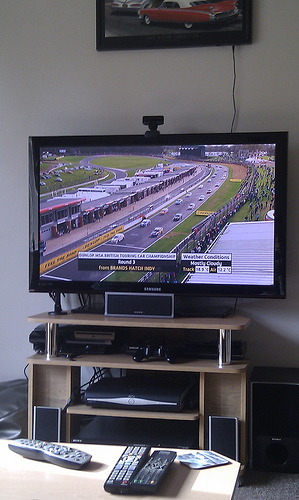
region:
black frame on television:
[14, 127, 282, 300]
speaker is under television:
[97, 281, 192, 328]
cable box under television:
[88, 375, 212, 430]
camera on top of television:
[139, 105, 168, 134]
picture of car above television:
[85, 0, 279, 46]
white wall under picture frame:
[45, 37, 147, 110]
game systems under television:
[32, 318, 233, 364]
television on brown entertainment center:
[18, 131, 272, 291]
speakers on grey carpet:
[240, 374, 293, 484]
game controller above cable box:
[134, 339, 188, 370]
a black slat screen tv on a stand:
[28, 125, 289, 304]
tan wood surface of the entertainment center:
[209, 372, 239, 396]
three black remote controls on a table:
[6, 430, 170, 496]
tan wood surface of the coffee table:
[23, 472, 76, 498]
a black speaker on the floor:
[246, 364, 297, 478]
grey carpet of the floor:
[246, 474, 285, 498]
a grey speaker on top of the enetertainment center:
[98, 287, 177, 322]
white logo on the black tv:
[137, 284, 166, 294]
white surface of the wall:
[261, 310, 283, 350]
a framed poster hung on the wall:
[80, 0, 261, 61]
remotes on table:
[0, 434, 243, 497]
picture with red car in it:
[89, 2, 256, 53]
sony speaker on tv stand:
[20, 287, 255, 480]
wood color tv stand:
[21, 349, 249, 483]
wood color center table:
[0, 436, 243, 497]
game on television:
[22, 110, 288, 301]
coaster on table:
[172, 448, 233, 470]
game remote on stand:
[22, 308, 247, 486]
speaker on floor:
[231, 373, 296, 497]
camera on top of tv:
[23, 111, 289, 301]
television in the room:
[20, 125, 293, 323]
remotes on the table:
[33, 430, 190, 493]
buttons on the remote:
[104, 438, 143, 489]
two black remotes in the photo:
[111, 436, 180, 493]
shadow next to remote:
[167, 469, 197, 498]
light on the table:
[205, 467, 228, 487]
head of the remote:
[56, 442, 99, 481]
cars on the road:
[136, 190, 207, 241]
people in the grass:
[246, 170, 267, 203]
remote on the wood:
[129, 334, 184, 366]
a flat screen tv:
[12, 118, 275, 311]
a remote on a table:
[79, 437, 160, 486]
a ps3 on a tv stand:
[10, 299, 150, 359]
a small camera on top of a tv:
[112, 102, 183, 150]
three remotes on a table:
[22, 418, 219, 494]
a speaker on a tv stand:
[86, 290, 214, 327]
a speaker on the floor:
[234, 361, 296, 483]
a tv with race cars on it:
[17, 105, 287, 320]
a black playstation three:
[31, 301, 160, 359]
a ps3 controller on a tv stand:
[126, 332, 195, 391]